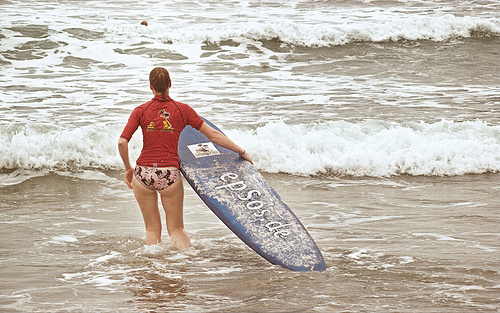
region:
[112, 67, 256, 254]
a woman wading into the ocean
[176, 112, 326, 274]
a surfboard under a woman's arm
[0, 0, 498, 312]
the ocean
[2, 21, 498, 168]
a wave rolling into shore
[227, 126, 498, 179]
frothy white sea foam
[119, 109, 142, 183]
a woman's arm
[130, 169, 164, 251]
a woman's lef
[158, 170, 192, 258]
a woman's leg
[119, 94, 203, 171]
a red t-shirt on a woman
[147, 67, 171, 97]
a woman's hair in a ponytail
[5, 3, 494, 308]
at the beach close to the shore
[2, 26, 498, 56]
large foam top wave coming to shore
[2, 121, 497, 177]
larger foam top wave closer to shore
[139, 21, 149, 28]
mans head sticking out of the ocean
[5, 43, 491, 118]
a lot of white foam on top of the water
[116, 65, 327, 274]
red hair woman looking at the man in the water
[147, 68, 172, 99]
red haired woman head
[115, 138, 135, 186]
red haired woman lower arm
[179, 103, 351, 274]
red haired woman arm and surfboard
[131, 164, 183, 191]
red haired woman bathing suit bottom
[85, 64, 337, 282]
a surfer entering the water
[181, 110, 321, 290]
a blue surf board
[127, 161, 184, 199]
floral bath suit bottoms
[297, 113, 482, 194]
waves in the water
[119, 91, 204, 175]
red top on a surfer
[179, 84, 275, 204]
right arm of a surfer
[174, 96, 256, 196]
a surf board in the right arm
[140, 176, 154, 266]
a leg of a surfer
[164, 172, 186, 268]
a right leg of a surfer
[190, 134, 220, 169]
a symbol on the board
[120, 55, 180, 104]
woman's hair is wet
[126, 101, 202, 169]
woman's shirt is red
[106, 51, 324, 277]
woman holding a surfboard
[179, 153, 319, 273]
sand on the surfboard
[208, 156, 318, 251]
white letters on surfboard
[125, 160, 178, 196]
woman wearing a bikini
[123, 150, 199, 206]
woman's bikini is pink and black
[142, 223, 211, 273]
woman's legs in water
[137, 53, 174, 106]
woman's hair in pony tail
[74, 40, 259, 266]
woman looking at waves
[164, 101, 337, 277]
A blue surfboard.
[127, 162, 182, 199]
A female surfer's butt.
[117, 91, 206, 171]
The red water shirt of a surfer.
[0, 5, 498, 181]
Some muddy ocean waves.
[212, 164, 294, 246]
German website address.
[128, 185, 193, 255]
The legs of a surfer.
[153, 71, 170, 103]
A surfer's tight ponytail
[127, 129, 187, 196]
The waist and hips of a surfer.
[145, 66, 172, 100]
A surfer's head.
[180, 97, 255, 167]
A surfer's right arm.